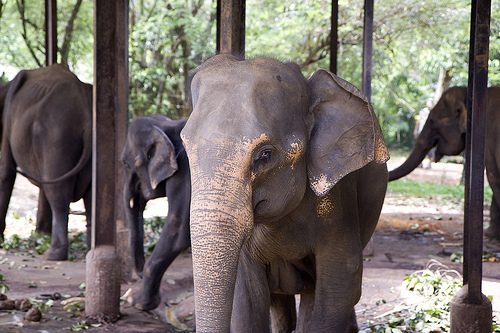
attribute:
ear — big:
[294, 71, 394, 180]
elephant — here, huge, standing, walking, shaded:
[157, 31, 387, 326]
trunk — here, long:
[183, 140, 250, 328]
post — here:
[462, 14, 495, 327]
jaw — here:
[262, 188, 302, 229]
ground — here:
[406, 193, 455, 330]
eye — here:
[246, 144, 283, 173]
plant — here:
[375, 54, 427, 107]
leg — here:
[115, 211, 193, 308]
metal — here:
[89, 19, 132, 205]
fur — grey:
[221, 77, 259, 112]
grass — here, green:
[409, 173, 468, 228]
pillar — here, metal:
[67, 24, 141, 248]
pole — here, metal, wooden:
[82, 3, 135, 316]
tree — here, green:
[393, 12, 494, 187]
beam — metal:
[458, 13, 491, 222]